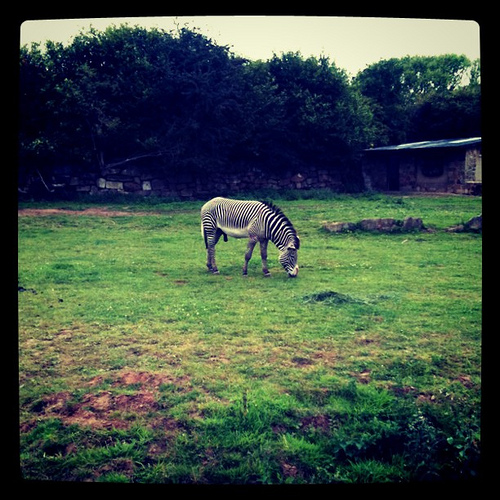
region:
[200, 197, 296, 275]
black and white striped zebra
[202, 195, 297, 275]
male zebra eating grass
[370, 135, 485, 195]
building in the background on the right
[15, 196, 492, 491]
grassy field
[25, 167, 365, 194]
stacked stone fence beyond the field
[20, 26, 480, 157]
green trees behind the fence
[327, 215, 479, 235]
large rocks in the middle of the grass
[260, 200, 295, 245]
zebra's black mane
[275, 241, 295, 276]
head of the zebra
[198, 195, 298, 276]
zebra with stripes eating alone in the field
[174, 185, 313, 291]
black and white zebra eating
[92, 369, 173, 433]
brown patches on the ground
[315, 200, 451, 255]
rock formation on the grass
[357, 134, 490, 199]
brown building in the background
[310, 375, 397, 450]
green grass on the ground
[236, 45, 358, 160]
green tree next to the building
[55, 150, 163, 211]
wood behind the zebra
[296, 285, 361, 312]
bunch of green grass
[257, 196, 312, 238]
black mane on the zebra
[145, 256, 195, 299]
brown patches on the ground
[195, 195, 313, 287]
a zebra eating grass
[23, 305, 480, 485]
brown and green grass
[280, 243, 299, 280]
the head of a zebra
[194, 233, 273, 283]
the legs of a zebra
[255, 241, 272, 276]
the front leg of a zebra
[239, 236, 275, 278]
the front legs of a zebra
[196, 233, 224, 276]
the rear legs of a zebra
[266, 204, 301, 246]
the neck of a zebra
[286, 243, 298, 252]
the ear of a zebra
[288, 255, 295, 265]
the eye of a zebra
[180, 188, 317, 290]
zebra standing on the grass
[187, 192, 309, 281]
black and white zebra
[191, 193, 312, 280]
zebra grazing in the grass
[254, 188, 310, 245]
black hair along the neck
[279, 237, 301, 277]
head bent down to the ground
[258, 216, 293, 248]
black and white stripes along the neck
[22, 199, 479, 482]
green grass on the ground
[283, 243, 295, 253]
ear on the side of the head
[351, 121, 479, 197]
small building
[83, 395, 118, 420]
patch of dirt in the grass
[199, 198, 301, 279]
black and white zebra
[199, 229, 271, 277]
four legs of zebra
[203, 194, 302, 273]
zebra with head down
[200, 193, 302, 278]
black and white zebra eating green grass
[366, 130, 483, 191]
little house with blue roof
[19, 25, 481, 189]
a bunch of trees on the back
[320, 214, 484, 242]
small brown stumps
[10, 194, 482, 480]
dark green grass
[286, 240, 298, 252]
small black and white right ear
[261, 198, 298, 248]
black hair on the loin